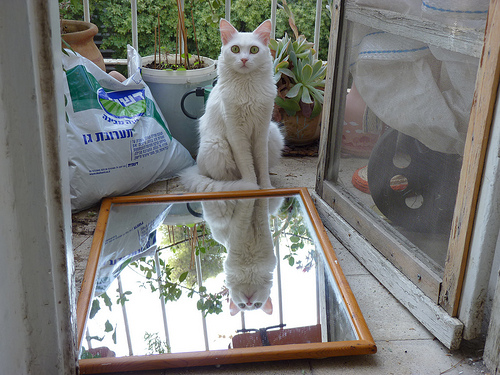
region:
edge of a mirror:
[354, 324, 374, 364]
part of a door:
[453, 242, 468, 284]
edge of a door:
[448, 265, 458, 292]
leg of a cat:
[232, 136, 237, 152]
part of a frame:
[348, 278, 368, 321]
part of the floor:
[394, 346, 396, 354]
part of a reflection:
[241, 270, 246, 279]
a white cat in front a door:
[5, 0, 491, 277]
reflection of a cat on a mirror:
[71, 185, 377, 362]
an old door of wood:
[311, 3, 499, 353]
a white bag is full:
[69, 48, 191, 205]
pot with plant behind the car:
[272, 33, 334, 168]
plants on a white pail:
[138, 7, 213, 137]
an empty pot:
[63, 15, 117, 70]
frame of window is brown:
[69, 176, 379, 369]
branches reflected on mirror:
[121, 244, 221, 329]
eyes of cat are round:
[223, 36, 267, 55]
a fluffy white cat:
[186, 18, 286, 189]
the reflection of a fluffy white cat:
[201, 198, 283, 317]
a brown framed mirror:
[81, 195, 378, 363]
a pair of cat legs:
[227, 111, 275, 190]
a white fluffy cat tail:
[181, 166, 255, 194]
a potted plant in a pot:
[270, 34, 330, 149]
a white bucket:
[141, 53, 212, 144]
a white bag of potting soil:
[58, 45, 194, 195]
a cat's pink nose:
[239, 56, 249, 66]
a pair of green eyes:
[228, 43, 260, 56]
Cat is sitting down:
[172, 13, 295, 198]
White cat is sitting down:
[175, 15, 295, 195]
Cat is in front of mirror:
[178, 14, 286, 194]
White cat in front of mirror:
[177, 12, 296, 198]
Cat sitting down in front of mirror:
[176, 12, 286, 194]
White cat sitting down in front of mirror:
[177, 14, 287, 197]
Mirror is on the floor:
[75, 187, 377, 372]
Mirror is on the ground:
[70, 185, 385, 373]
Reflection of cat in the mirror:
[192, 194, 287, 316]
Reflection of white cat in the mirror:
[193, 195, 288, 320]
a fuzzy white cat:
[181, 16, 286, 191]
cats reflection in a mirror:
[203, 196, 284, 328]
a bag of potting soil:
[58, 51, 180, 217]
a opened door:
[324, 19, 499, 346]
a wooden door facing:
[36, 0, 75, 355]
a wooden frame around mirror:
[75, 183, 377, 368]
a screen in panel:
[337, 38, 482, 280]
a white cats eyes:
[227, 44, 267, 61]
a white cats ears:
[215, 14, 277, 48]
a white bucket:
[137, 53, 221, 155]